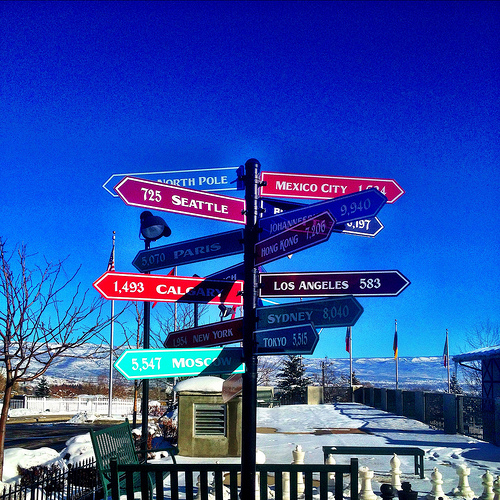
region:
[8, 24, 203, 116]
A blue sky background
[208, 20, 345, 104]
A blue sky background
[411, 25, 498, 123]
A blue sky background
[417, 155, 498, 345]
A blue sky background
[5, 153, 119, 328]
A blue sky background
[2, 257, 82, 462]
A dry tree branch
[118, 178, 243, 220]
A street direction sign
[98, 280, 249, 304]
A street direction sign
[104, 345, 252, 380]
A street direction sign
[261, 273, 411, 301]
A street direction sign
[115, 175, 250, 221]
A Seattle street sign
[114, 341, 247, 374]
A Moscow street sign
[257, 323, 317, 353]
A Tokyo street sign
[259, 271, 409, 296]
A Los Angeles street sign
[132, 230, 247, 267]
A Paris street sign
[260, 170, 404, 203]
A Mexico City street sign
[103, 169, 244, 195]
A north pole street sign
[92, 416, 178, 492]
A green bench outside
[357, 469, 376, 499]
A rook chess piece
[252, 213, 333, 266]
A Hong Kong street sign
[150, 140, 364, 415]
the view is at a sighnposter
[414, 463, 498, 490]
the plates are white in color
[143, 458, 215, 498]
the bench is black in color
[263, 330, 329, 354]
the words are written on a blie cable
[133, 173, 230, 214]
words written on a pink plate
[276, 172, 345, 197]
word ar written on a red plate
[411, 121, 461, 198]
the sky is clar blue in color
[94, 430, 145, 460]
the bench is green in color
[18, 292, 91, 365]
the branches are dried and brown in color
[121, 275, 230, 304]
the words are written in white color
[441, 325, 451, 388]
flag on gate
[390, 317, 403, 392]
flag on gate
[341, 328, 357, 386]
flag on gate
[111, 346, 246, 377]
street sign on pole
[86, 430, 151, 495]
bench next to gate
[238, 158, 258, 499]
gate next to pole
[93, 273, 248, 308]
street sign on pole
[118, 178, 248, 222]
street sign on pole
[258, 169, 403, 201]
street sign on pole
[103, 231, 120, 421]
flag in snow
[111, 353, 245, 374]
A bight photo background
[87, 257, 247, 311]
A bight photo background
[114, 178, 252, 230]
A bight photo background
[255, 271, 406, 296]
A bight photo background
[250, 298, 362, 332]
A bight photo background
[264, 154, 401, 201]
A bight photo background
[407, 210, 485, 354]
A blue cloud background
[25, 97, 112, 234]
A blue cloud background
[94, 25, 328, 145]
A blue cloud background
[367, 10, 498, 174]
A blue cloud background